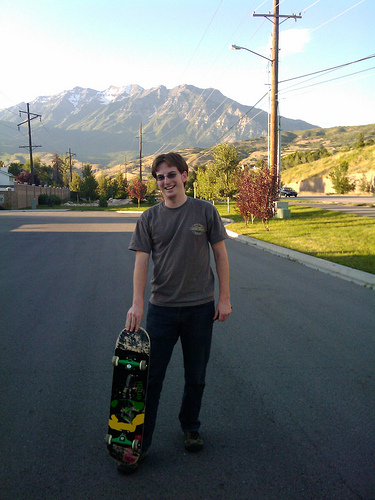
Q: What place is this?
A: It is a street.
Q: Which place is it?
A: It is a street.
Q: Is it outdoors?
A: Yes, it is outdoors.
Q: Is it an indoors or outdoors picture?
A: It is outdoors.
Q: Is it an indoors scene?
A: No, it is outdoors.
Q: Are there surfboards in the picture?
A: No, there are no surfboards.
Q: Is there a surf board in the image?
A: No, there are no surfboards.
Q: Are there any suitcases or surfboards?
A: No, there are no surfboards or suitcases.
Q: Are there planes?
A: No, there are no planes.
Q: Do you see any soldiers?
A: No, there are no soldiers.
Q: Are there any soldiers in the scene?
A: No, there are no soldiers.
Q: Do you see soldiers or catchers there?
A: No, there are no soldiers or catchers.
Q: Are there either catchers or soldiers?
A: No, there are no soldiers or catchers.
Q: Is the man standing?
A: Yes, the man is standing.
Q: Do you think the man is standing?
A: Yes, the man is standing.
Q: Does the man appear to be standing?
A: Yes, the man is standing.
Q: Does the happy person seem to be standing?
A: Yes, the man is standing.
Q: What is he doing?
A: The man is standing.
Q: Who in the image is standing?
A: The man is standing.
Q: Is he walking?
A: No, the man is standing.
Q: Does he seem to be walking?
A: No, the man is standing.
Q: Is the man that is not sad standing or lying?
A: The man is standing.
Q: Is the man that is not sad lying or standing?
A: The man is standing.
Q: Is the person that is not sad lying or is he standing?
A: The man is standing.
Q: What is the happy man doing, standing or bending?
A: The man is standing.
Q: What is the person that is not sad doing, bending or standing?
A: The man is standing.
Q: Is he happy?
A: Yes, the man is happy.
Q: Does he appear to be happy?
A: Yes, the man is happy.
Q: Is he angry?
A: No, the man is happy.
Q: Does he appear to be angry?
A: No, the man is happy.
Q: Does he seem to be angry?
A: No, the man is happy.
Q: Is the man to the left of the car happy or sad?
A: The man is happy.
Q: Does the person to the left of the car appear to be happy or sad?
A: The man is happy.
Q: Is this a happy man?
A: Yes, this is a happy man.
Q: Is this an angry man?
A: No, this is a happy man.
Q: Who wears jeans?
A: The man wears jeans.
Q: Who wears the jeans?
A: The man wears jeans.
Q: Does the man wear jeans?
A: Yes, the man wears jeans.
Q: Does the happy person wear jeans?
A: Yes, the man wears jeans.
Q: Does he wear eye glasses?
A: No, the man wears jeans.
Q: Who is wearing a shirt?
A: The man is wearing a shirt.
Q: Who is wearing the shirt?
A: The man is wearing a shirt.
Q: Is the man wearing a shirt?
A: Yes, the man is wearing a shirt.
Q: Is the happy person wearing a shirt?
A: Yes, the man is wearing a shirt.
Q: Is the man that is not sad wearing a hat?
A: No, the man is wearing a shirt.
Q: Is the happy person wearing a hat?
A: No, the man is wearing a shirt.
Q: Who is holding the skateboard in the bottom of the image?
A: The man is holding the skateboard.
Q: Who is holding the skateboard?
A: The man is holding the skateboard.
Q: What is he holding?
A: The man is holding the skateboard.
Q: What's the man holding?
A: The man is holding the skateboard.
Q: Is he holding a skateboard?
A: Yes, the man is holding a skateboard.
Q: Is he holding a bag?
A: No, the man is holding a skateboard.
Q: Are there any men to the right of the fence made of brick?
A: Yes, there is a man to the right of the fence.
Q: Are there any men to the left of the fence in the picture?
A: No, the man is to the right of the fence.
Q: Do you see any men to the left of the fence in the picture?
A: No, the man is to the right of the fence.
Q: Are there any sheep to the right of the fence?
A: No, there is a man to the right of the fence.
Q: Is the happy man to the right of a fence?
A: Yes, the man is to the right of a fence.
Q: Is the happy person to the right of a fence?
A: Yes, the man is to the right of a fence.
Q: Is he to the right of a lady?
A: No, the man is to the right of a fence.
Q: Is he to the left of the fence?
A: No, the man is to the right of the fence.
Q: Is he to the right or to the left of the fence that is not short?
A: The man is to the right of the fence.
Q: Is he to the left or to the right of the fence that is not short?
A: The man is to the right of the fence.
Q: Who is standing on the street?
A: The man is standing on the street.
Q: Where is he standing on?
A: The man is standing on the street.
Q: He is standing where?
A: The man is standing on the street.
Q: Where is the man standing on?
A: The man is standing on the street.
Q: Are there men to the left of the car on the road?
A: Yes, there is a man to the left of the car.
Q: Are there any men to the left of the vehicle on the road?
A: Yes, there is a man to the left of the car.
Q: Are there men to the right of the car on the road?
A: No, the man is to the left of the car.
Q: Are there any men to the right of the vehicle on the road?
A: No, the man is to the left of the car.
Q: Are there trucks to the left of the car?
A: No, there is a man to the left of the car.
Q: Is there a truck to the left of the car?
A: No, there is a man to the left of the car.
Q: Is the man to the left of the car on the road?
A: Yes, the man is to the left of the car.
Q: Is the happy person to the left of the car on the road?
A: Yes, the man is to the left of the car.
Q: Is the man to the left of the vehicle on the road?
A: Yes, the man is to the left of the car.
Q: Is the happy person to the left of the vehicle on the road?
A: Yes, the man is to the left of the car.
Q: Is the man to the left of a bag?
A: No, the man is to the left of the car.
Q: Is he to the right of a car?
A: No, the man is to the left of a car.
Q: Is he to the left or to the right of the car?
A: The man is to the left of the car.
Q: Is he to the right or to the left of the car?
A: The man is to the left of the car.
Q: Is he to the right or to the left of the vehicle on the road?
A: The man is to the left of the car.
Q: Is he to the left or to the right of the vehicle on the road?
A: The man is to the left of the car.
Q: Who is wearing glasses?
A: The man is wearing glasses.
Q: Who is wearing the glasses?
A: The man is wearing glasses.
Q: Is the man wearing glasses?
A: Yes, the man is wearing glasses.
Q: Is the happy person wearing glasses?
A: Yes, the man is wearing glasses.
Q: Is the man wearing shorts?
A: No, the man is wearing glasses.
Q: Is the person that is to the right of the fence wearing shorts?
A: No, the man is wearing glasses.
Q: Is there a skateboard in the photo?
A: Yes, there is a skateboard.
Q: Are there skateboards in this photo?
A: Yes, there is a skateboard.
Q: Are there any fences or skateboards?
A: Yes, there is a skateboard.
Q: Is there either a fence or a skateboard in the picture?
A: Yes, there is a skateboard.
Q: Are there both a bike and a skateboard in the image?
A: No, there is a skateboard but no bikes.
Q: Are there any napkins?
A: No, there are no napkins.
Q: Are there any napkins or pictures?
A: No, there are no napkins or pictures.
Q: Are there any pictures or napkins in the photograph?
A: No, there are no napkins or pictures.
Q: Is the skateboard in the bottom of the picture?
A: Yes, the skateboard is in the bottom of the image.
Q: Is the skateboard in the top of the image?
A: No, the skateboard is in the bottom of the image.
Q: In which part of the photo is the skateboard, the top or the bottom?
A: The skateboard is in the bottom of the image.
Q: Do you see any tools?
A: No, there are no tools.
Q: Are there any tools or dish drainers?
A: No, there are no tools or dish drainers.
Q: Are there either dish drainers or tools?
A: No, there are no tools or dish drainers.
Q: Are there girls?
A: No, there are no girls.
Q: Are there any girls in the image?
A: No, there are no girls.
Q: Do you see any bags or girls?
A: No, there are no girls or bags.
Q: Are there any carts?
A: No, there are no carts.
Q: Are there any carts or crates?
A: No, there are no carts or crates.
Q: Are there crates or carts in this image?
A: No, there are no carts or crates.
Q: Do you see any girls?
A: No, there are no girls.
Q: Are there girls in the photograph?
A: No, there are no girls.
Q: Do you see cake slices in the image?
A: No, there are no cake slices.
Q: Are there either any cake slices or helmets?
A: No, there are no cake slices or helmets.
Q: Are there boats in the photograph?
A: No, there are no boats.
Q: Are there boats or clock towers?
A: No, there are no boats or clock towers.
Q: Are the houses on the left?
A: Yes, the houses are on the left of the image.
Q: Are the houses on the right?
A: No, the houses are on the left of the image.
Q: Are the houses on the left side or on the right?
A: The houses are on the left of the image.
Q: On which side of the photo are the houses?
A: The houses are on the left of the image.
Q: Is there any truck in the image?
A: No, there are no trucks.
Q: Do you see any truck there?
A: No, there are no trucks.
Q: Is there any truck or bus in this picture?
A: No, there are no trucks or buses.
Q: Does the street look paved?
A: Yes, the street is paved.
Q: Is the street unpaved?
A: No, the street is paved.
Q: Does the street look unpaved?
A: No, the street is paved.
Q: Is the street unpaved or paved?
A: The street is paved.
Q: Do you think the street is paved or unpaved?
A: The street is paved.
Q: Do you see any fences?
A: Yes, there is a fence.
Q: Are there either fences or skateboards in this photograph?
A: Yes, there is a fence.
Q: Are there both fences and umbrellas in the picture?
A: No, there is a fence but no umbrellas.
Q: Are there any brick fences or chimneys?
A: Yes, there is a brick fence.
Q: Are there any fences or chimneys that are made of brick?
A: Yes, the fence is made of brick.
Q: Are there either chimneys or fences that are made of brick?
A: Yes, the fence is made of brick.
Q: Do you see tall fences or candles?
A: Yes, there is a tall fence.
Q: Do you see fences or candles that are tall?
A: Yes, the fence is tall.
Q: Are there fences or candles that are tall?
A: Yes, the fence is tall.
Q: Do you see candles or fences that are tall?
A: Yes, the fence is tall.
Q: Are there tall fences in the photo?
A: Yes, there is a tall fence.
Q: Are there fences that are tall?
A: Yes, there is a fence that is tall.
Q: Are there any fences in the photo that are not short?
A: Yes, there is a tall fence.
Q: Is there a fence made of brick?
A: Yes, there is a fence that is made of brick.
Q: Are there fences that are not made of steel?
A: Yes, there is a fence that is made of brick.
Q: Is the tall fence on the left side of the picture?
A: Yes, the fence is on the left of the image.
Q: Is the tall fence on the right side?
A: No, the fence is on the left of the image.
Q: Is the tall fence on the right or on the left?
A: The fence is on the left of the image.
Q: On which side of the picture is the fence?
A: The fence is on the left of the image.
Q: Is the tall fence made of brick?
A: Yes, the fence is made of brick.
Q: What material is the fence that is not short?
A: The fence is made of brick.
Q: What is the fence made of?
A: The fence is made of brick.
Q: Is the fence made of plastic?
A: No, the fence is made of brick.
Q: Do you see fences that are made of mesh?
A: No, there is a fence but it is made of brick.